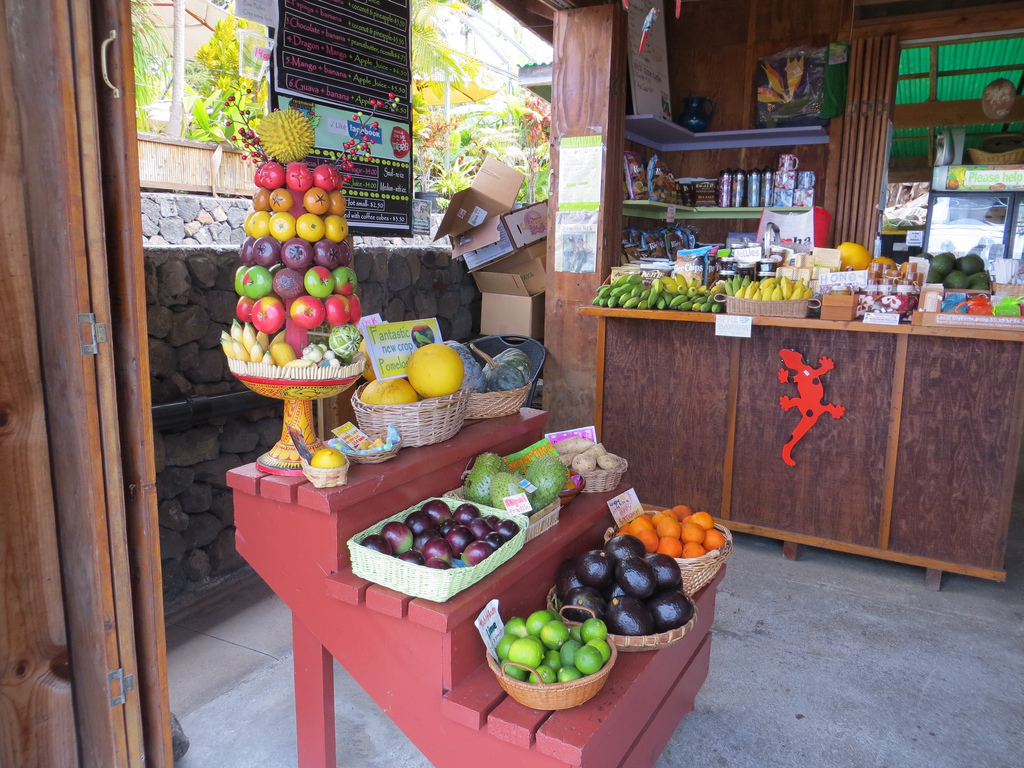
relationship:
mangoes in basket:
[354, 467, 544, 620] [354, 467, 544, 620]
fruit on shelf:
[483, 613, 622, 717] [599, 88, 858, 290]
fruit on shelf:
[615, 502, 741, 598] [599, 88, 858, 290]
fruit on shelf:
[339, 489, 525, 608] [599, 88, 858, 290]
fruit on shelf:
[462, 442, 584, 531] [599, 88, 858, 290]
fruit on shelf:
[341, 338, 465, 453] [599, 88, 858, 290]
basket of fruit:
[335, 467, 535, 614] [353, 478, 644, 600]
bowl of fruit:
[477, 594, 615, 705] [504, 616, 615, 664]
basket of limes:
[458, 591, 623, 708] [500, 594, 595, 690]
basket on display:
[458, 591, 623, 708] [215, 341, 736, 761]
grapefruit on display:
[351, 347, 482, 409] [215, 341, 736, 761]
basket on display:
[352, 328, 469, 443] [215, 341, 736, 761]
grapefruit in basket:
[351, 347, 482, 409] [352, 328, 469, 443]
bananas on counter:
[579, 248, 856, 328] [577, 288, 1021, 571]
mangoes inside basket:
[371, 509, 423, 561] [328, 487, 538, 622]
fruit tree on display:
[223, 101, 369, 380] [179, 101, 754, 763]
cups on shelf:
[690, 152, 830, 211] [598, 179, 856, 229]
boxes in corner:
[437, 139, 551, 365] [421, 81, 610, 535]